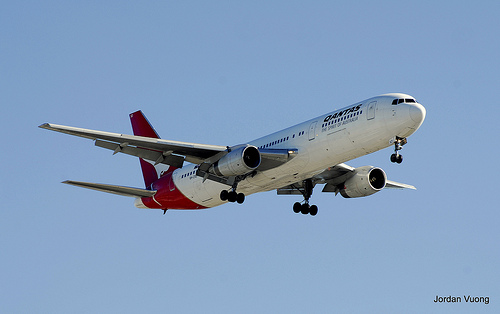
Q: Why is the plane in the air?
A: It is flying.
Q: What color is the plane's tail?
A: Red.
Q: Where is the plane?
A: In the sky.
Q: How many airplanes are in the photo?
A: One.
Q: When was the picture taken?
A: During the day.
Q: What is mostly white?
A: The airplane.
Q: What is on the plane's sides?
A: Wings.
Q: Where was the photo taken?
A: In the air.